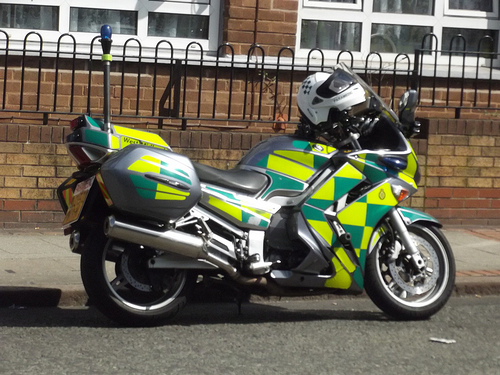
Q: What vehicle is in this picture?
A: A motorcycle.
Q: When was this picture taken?
A: Daytime.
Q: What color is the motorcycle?
A: Green and yellow.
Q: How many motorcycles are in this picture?
A: One.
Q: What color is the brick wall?
A: Brown and red.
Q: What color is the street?
A: Gray.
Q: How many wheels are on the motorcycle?
A: Two.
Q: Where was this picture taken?
A: The street.